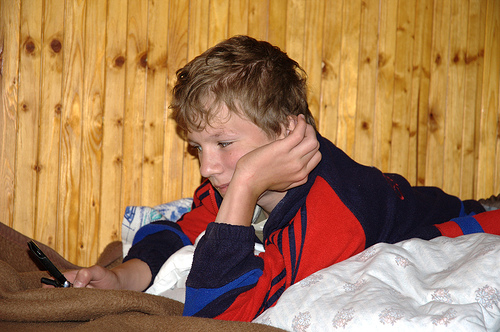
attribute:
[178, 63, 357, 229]
boy — laying, looking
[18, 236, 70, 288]
phone — black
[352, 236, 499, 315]
bed — white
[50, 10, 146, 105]
wall — brown, wood